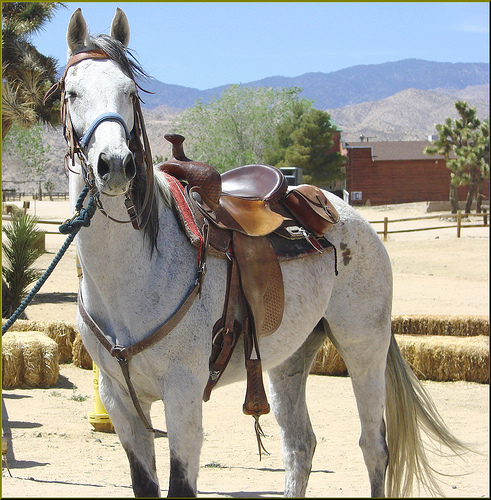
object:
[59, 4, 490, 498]
horse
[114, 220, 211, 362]
straps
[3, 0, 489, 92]
sky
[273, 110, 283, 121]
leaves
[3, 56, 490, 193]
mountains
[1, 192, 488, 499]
ground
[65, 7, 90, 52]
ears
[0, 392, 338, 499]
shadow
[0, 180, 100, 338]
rope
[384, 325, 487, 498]
tail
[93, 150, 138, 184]
nose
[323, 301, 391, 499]
legs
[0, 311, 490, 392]
hay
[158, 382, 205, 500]
front legs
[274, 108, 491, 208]
building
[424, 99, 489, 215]
tree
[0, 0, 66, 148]
palm tree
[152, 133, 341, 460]
saddle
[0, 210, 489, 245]
fence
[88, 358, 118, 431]
barrel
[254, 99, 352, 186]
trees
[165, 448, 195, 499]
spots